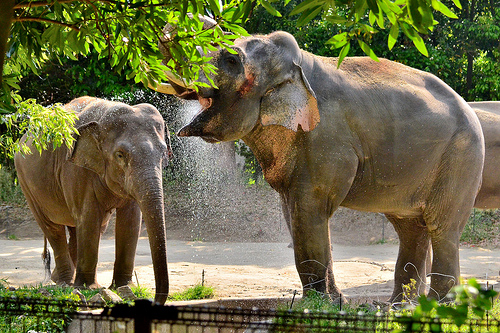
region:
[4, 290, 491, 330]
a wire gate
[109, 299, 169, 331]
a black post that connects gate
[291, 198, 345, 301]
an elephant's front leg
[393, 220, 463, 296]
an elephant's back legs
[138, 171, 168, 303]
a trunk of an elephant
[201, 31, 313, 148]
an elephant's face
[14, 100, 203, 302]
a baby elephant standing on cement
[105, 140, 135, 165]
a left eye of an elephant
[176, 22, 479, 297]
an elephant in the trees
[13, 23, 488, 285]
two elephants inside a pen area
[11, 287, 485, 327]
the top of the fence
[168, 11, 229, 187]
a spray of water from the elephant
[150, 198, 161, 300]
the trunk of the elephant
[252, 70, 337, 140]
elephant ear with a piece missing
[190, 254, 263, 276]
a dirt floor for the animals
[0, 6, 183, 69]
a very green tree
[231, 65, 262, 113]
a marking on the elephant's face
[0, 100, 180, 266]
the youngest elephant in the picture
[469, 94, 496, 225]
a third elephant that is not clearly seen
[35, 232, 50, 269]
elephant's tail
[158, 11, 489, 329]
elephant is eating leaves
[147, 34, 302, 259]
water splashing behind elephants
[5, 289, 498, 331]
fence is made of metal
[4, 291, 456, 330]
the fence is black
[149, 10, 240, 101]
elephant's trunk is curled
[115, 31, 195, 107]
elephant's tusk is white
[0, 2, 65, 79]
tree branch is brown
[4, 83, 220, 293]
the elephant is walking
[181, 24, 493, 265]
the elephant is dirty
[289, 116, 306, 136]
elephant's ear is split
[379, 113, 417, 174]
part of a stomach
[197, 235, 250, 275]
part of a floor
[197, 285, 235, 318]
edge of a fence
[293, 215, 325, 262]
part of a leg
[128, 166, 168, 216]
part of a trunk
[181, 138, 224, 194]
part of a stone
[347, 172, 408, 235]
edge of a stomach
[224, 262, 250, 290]
part of a ground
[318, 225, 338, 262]
edge of a leg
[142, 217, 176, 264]
part of a trunk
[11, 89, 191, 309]
grey baby elephant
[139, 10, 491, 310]
big momma elephant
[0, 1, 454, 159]
leafy green trees in the foreground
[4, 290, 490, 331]
blurry black metal fence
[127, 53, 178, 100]
big ivory elephant tusk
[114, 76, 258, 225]
water spraying out of the elephant's trunk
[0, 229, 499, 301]
dry grey dirt ground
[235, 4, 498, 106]
dense trees in the background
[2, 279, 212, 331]
green grass and rocks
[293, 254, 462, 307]
dead dried up vines